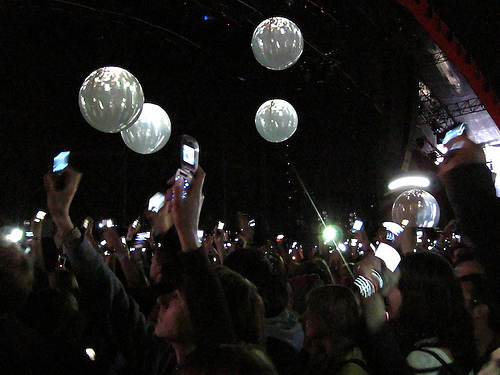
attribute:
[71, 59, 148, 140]
ball — shiny, silver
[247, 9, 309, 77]
lamp — floating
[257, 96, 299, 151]
lamp — floating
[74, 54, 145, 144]
lamp — floating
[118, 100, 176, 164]
lamp — floating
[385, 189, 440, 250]
lamp — floating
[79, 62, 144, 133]
ball — silver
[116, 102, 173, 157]
ball — silver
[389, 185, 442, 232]
ball — silver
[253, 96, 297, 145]
ball — silver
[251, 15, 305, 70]
ball — silver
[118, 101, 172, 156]
paper lamp — floating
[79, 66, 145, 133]
paper lamp — floating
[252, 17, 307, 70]
lamp — floating, paper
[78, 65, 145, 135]
lamp — paper, floating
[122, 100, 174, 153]
lamp — paper, floating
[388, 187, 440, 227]
silver ball — shiny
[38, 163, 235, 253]
arms — extended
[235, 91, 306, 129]
ball — shiny , silver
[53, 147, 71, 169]
screen — lit